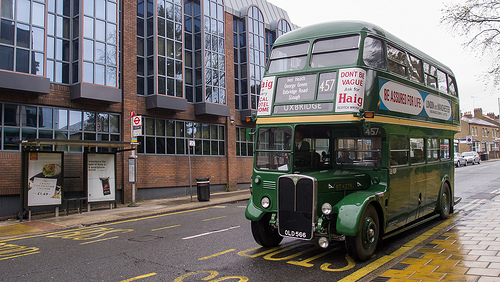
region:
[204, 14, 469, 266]
a double decker bus driving down a city street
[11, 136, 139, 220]
a bus stop on the sidewalk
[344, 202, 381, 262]
a wheel of a bus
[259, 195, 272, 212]
the headlight of a bus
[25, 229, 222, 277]
a city street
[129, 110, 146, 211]
a sign posted next to a busstop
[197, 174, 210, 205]
a trash can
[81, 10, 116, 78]
glass windows of a building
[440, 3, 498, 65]
a leafless tree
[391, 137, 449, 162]
the windows on a bus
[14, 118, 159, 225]
a bus stop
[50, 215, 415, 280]
stop written in yellow on the tar road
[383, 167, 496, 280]
yellow brick sidewalk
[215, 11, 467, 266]
a green bus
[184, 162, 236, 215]
a black trash can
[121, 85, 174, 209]
red and white street signs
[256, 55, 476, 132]
advertisements on a green bus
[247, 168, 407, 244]
white numbers on a green bus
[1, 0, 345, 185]
big windows on a brick building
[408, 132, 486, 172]
cars parked on the side of the road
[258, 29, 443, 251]
The bus is green.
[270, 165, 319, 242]
The grill of the bus is black.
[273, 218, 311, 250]
Number on the grill of the bus.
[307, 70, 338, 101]
The bus is number 457.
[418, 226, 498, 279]
The sidewalk is yellow.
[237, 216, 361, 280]
Stop underneath the bus.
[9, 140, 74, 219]
Sign on a board.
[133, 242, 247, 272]
Yellow lines on the street.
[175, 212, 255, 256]
White line on the street.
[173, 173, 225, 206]
Trashcan next to a pole.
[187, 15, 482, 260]
green double-decker bus with yellow stripe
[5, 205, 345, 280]
yellow printing on dark street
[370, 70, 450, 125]
advertisements on the side of the bus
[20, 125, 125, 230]
advertisements on bus-stop partition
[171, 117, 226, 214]
pole and garbage can near each other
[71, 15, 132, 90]
windows reflecting a tree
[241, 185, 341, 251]
round white lights on front of bus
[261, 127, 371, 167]
passengers in bus darkness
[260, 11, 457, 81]
curved roof of bus top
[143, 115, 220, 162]
two rows of windows on building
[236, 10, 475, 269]
bus on a street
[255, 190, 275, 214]
headlight on a vehicle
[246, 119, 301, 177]
front windshield on a vehicle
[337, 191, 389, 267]
front wheel on a vehicle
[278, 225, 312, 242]
licence plate on a vehicle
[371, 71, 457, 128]
advertising sign on a vehicle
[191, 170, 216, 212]
trash container on a sidewalk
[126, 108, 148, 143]
sign on a pole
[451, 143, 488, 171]
vehicles parked on a street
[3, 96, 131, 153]
windows on a building